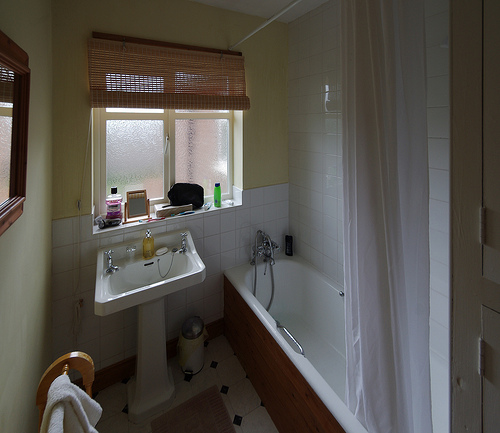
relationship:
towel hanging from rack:
[37, 370, 105, 432] [29, 346, 100, 430]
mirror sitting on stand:
[128, 199, 147, 214] [123, 195, 156, 226]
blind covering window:
[82, 25, 256, 114] [82, 25, 252, 233]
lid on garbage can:
[181, 311, 206, 341] [177, 315, 207, 382]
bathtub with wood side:
[221, 228, 378, 431] [219, 272, 346, 432]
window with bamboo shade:
[86, 37, 243, 212] [91, 41, 250, 110]